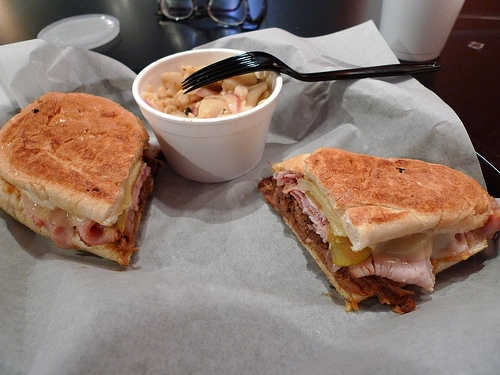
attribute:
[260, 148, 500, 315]
panini — brown, toasted, cut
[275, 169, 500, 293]
ham — cooked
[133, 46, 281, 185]
cup — small, styrofoam, white, full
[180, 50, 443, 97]
fork — plastic, black, platic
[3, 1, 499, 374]
table — black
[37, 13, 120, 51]
lid — platic, white, plastic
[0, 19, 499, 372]
paper — white, translucent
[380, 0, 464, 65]
cup — white, styrofoam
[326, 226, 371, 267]
vegetable — yellow